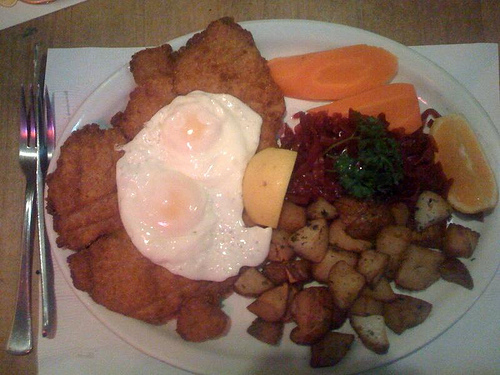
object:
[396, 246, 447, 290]
potatoes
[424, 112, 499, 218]
orange slice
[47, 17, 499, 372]
plate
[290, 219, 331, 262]
potatoes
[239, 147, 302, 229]
lemon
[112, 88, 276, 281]
eggs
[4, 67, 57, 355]
fork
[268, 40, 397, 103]
carrots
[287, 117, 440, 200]
salsa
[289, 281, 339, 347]
chicken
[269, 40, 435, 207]
veggies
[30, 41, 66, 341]
knife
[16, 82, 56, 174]
tines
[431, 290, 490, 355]
edge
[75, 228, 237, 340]
beef